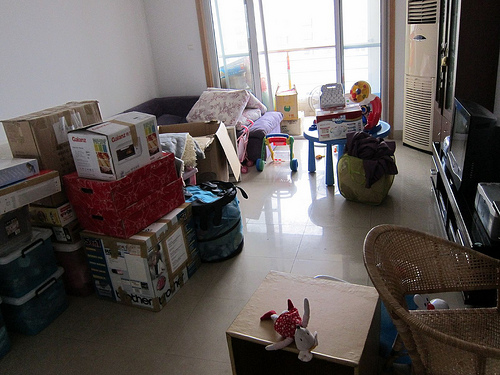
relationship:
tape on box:
[141, 225, 161, 253] [101, 202, 202, 313]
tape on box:
[153, 214, 178, 224] [101, 202, 202, 313]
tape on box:
[173, 200, 194, 208] [101, 202, 202, 313]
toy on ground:
[257, 127, 299, 172] [262, 170, 301, 178]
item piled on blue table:
[315, 80, 347, 111] [305, 126, 319, 142]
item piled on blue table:
[348, 79, 370, 99] [305, 126, 319, 142]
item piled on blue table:
[315, 103, 368, 143] [305, 126, 319, 142]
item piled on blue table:
[367, 95, 385, 127] [305, 126, 319, 142]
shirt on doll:
[272, 303, 308, 345] [254, 293, 333, 371]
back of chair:
[360, 220, 439, 330] [356, 234, 423, 289]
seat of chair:
[452, 314, 484, 341] [355, 221, 485, 370]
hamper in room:
[334, 151, 397, 202] [4, 2, 478, 361]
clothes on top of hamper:
[345, 131, 397, 188] [336, 154, 395, 207]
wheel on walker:
[288, 157, 299, 171] [253, 132, 298, 172]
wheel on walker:
[253, 156, 265, 171] [253, 131, 298, 176]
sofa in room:
[116, 94, 203, 127] [4, 2, 478, 361]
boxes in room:
[2, 102, 201, 324] [4, 2, 478, 361]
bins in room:
[0, 118, 212, 313] [4, 2, 478, 361]